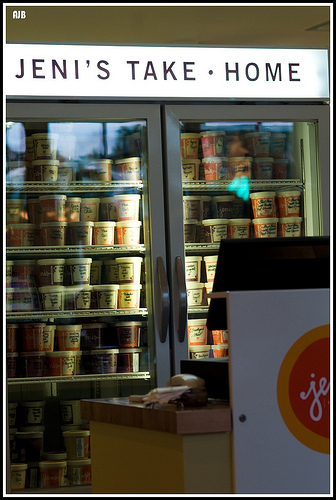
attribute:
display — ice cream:
[14, 115, 321, 434]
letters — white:
[299, 373, 328, 421]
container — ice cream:
[249, 191, 277, 217]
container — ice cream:
[202, 219, 228, 243]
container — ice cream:
[200, 128, 225, 155]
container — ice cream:
[112, 193, 140, 219]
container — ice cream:
[39, 193, 67, 222]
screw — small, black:
[236, 410, 248, 423]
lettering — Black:
[78, 264, 88, 278]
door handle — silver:
[174, 255, 190, 347]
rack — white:
[6, 180, 145, 191]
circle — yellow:
[271, 326, 332, 470]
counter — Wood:
[76, 388, 232, 493]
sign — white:
[8, 46, 333, 97]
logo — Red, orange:
[257, 336, 329, 403]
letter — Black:
[15, 59, 302, 84]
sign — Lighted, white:
[4, 43, 335, 99]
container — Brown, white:
[202, 218, 229, 242]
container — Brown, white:
[227, 216, 251, 236]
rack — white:
[264, 175, 286, 188]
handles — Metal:
[155, 255, 188, 341]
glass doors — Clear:
[8, 100, 328, 494]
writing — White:
[297, 368, 333, 421]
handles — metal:
[141, 242, 189, 353]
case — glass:
[6, 103, 331, 498]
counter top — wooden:
[55, 377, 243, 467]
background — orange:
[276, 325, 330, 455]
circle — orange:
[290, 335, 327, 438]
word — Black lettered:
[224, 58, 300, 84]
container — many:
[117, 217, 143, 242]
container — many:
[114, 318, 140, 348]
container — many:
[65, 255, 91, 280]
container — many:
[29, 129, 60, 161]